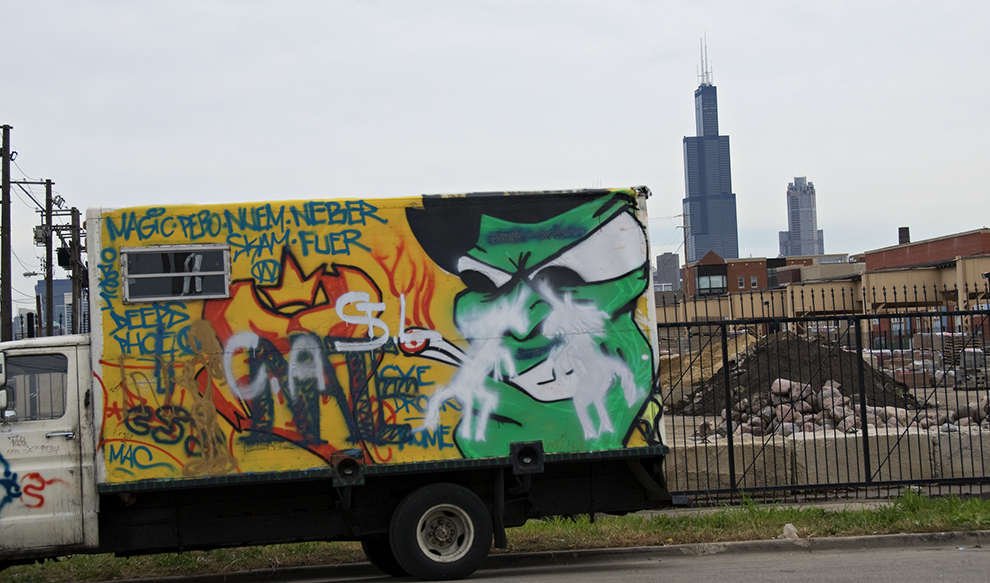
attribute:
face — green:
[401, 192, 653, 462]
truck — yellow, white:
[16, 181, 678, 557]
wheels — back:
[352, 484, 499, 557]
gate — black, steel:
[682, 277, 961, 516]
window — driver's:
[9, 347, 73, 444]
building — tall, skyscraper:
[675, 36, 739, 273]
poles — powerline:
[10, 117, 83, 320]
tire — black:
[390, 484, 498, 570]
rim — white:
[414, 500, 477, 561]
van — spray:
[23, 176, 676, 564]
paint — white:
[219, 277, 649, 446]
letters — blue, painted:
[99, 199, 396, 299]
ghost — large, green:
[408, 189, 660, 464]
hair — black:
[396, 189, 599, 264]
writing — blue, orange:
[9, 450, 52, 523]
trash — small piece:
[772, 502, 806, 545]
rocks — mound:
[718, 374, 901, 446]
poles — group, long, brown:
[3, 151, 76, 322]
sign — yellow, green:
[81, 187, 667, 496]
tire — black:
[381, 471, 496, 571]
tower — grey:
[676, 34, 746, 307]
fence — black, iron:
[662, 286, 960, 505]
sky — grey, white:
[19, 10, 958, 303]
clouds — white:
[230, 30, 408, 174]